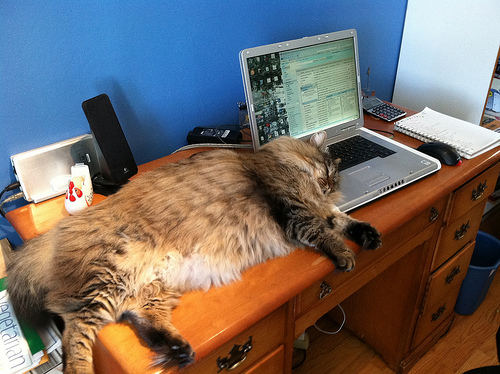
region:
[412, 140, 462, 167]
A black computer mouse.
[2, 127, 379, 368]
A cat on a desk.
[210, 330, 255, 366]
A handle of a desk drawer.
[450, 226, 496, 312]
A garbage can on the floor.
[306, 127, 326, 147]
The ear on a cat.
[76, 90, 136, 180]
A black computer speaker.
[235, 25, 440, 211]
A open laptop on a desk.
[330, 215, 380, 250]
The paw on a cat.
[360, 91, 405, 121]
A calculator on a desk.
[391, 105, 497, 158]
A note book on a desk.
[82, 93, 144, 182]
a large black and silver speaker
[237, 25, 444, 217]
a silver laptop computer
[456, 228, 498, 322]
a small blue trashcan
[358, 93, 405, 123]
a gray desktop calculator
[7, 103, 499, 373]
a large brown desk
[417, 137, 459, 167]
a black computer mouse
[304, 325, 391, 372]
a section of brown hardwood floor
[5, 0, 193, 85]
part of a blue painted wall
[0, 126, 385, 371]
a large black and gray cat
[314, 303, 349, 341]
a white cord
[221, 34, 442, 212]
laptop on a desk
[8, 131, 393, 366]
cat laying on a desk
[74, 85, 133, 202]
speaker on a desk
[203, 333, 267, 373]
handle on a drawer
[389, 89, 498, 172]
notebook on a desk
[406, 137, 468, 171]
mouse next to laptop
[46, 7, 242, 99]
blue painted wall in an office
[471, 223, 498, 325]
waste basket on floor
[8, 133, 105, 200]
internet box on desk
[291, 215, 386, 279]
front legs of a cat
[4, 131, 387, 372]
this is a really big cat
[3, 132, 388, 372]
the cat is sprawled on a desk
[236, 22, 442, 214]
the cat is using a laptop computer as a pillow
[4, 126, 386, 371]
the cat has long fur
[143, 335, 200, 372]
tufts of long fur between the toes is consistent with a longhair cat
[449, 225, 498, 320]
wastebasket next to the desk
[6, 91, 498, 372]
this beautiful wood desk has brass fittings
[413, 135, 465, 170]
computer mouse next to the laptop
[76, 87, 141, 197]
speaker to the left of the laptop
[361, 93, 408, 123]
calculator to the right of the laptop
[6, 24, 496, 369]
A large cat lying on a desk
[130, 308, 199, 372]
The back foot of a cat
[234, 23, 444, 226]
A laptop computer with a cat resting on it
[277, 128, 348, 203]
The head of a cat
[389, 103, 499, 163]
A spiral bound notebook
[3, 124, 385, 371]
A big fluffy tabby cat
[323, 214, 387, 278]
The front paws of a cat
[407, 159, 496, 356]
The right side drawers of a desk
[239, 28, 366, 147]
The screen of a laptop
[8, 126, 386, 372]
A cat sleeping on it's side